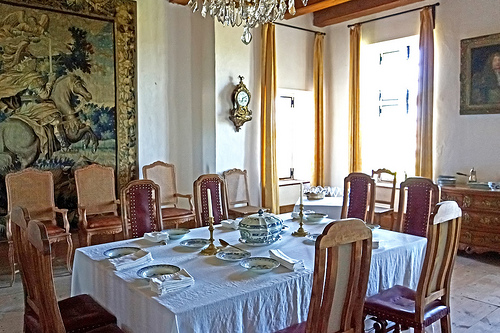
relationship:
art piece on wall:
[2, 0, 144, 229] [0, 3, 213, 272]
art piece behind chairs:
[2, 0, 144, 229] [2, 156, 197, 275]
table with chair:
[58, 212, 436, 331] [363, 198, 463, 330]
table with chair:
[58, 212, 436, 331] [280, 219, 374, 331]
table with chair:
[58, 212, 436, 331] [390, 177, 440, 236]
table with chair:
[58, 212, 436, 331] [339, 171, 375, 222]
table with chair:
[58, 212, 436, 331] [10, 207, 117, 330]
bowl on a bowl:
[141, 255, 191, 295] [234, 247, 280, 279]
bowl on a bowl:
[141, 255, 191, 295] [152, 225, 197, 247]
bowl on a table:
[141, 255, 191, 295] [64, 208, 466, 332]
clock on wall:
[228, 75, 252, 131] [215, 45, 260, 167]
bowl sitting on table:
[136, 262, 183, 282] [117, 203, 428, 313]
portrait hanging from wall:
[457, 31, 496, 112] [332, 3, 497, 245]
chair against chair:
[3, 166, 73, 286] [72, 162, 129, 246]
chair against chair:
[3, 166, 73, 286] [140, 157, 194, 228]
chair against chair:
[3, 166, 73, 286] [221, 167, 266, 217]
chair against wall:
[3, 166, 73, 286] [2, 0, 330, 277]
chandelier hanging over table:
[184, 0, 316, 47] [58, 212, 436, 331]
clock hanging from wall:
[228, 75, 252, 131] [213, 10, 333, 210]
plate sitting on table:
[252, 250, 277, 280] [58, 212, 436, 331]